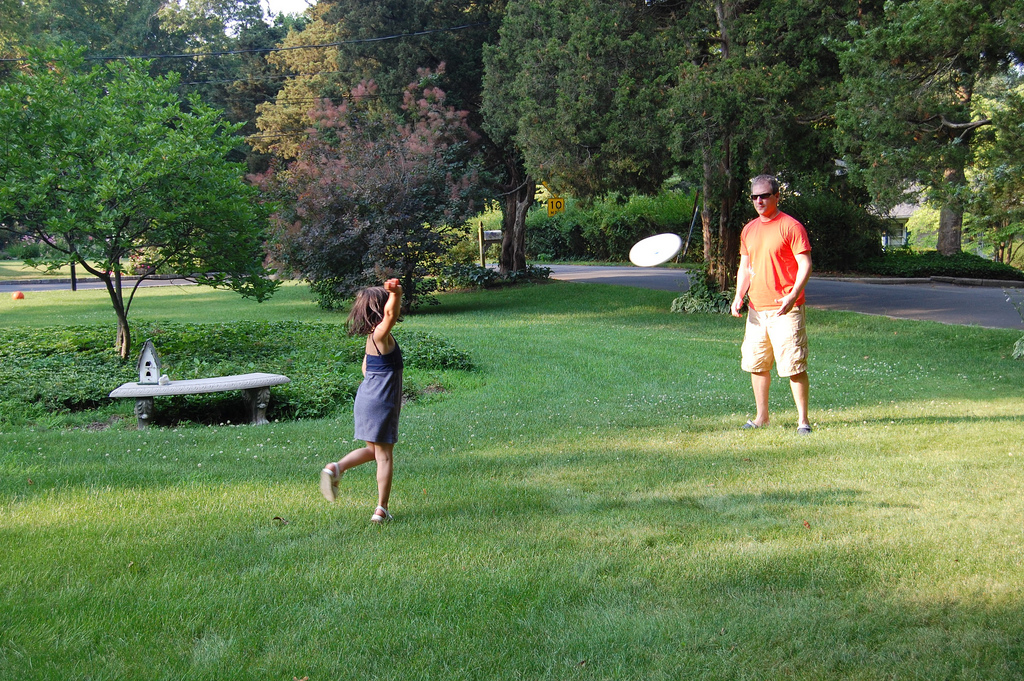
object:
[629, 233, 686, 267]
frisbee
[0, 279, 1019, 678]
grass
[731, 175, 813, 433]
man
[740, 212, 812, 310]
orange shirt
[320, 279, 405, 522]
kid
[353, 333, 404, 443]
dress